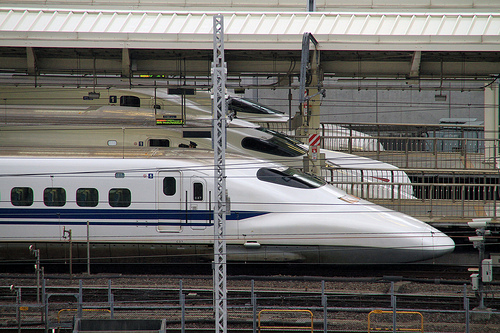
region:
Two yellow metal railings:
[254, 305, 426, 331]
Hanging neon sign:
[150, 82, 187, 129]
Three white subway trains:
[1, 77, 456, 271]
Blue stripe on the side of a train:
[1, 206, 268, 229]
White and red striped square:
[307, 130, 321, 147]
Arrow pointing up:
[107, 93, 118, 104]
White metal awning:
[1, 4, 498, 52]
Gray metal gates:
[250, 118, 498, 225]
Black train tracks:
[4, 280, 499, 315]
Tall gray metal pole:
[207, 14, 238, 331]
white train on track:
[1, 164, 478, 267]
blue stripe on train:
[12, 194, 239, 259]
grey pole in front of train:
[195, 63, 241, 323]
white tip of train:
[379, 193, 465, 255]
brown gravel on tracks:
[200, 273, 402, 305]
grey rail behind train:
[329, 154, 497, 236]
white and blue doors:
[151, 139, 186, 219]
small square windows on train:
[15, 181, 142, 206]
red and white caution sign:
[286, 131, 336, 168]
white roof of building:
[4, 6, 469, 62]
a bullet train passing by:
[1, 144, 462, 279]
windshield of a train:
[257, 159, 327, 194]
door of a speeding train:
[150, 166, 186, 236]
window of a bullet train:
[8, 182, 134, 210]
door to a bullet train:
[186, 175, 214, 231]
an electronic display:
[152, 114, 186, 130]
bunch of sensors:
[462, 211, 494, 320]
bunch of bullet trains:
[5, 79, 462, 267]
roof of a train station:
[7, 10, 484, 42]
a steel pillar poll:
[203, 9, 240, 331]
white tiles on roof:
[311, 7, 433, 49]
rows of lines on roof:
[54, 9, 131, 39]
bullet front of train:
[419, 222, 463, 254]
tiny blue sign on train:
[138, 170, 156, 182]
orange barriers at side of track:
[253, 297, 408, 331]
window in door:
[157, 172, 182, 202]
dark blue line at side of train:
[8, 207, 256, 228]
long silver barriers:
[329, 153, 481, 218]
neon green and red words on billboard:
[144, 116, 197, 128]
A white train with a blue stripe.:
[1, 153, 456, 267]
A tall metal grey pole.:
[212, 13, 229, 332]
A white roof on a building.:
[1, 2, 498, 53]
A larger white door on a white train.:
[155, 166, 184, 233]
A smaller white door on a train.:
[188, 175, 206, 229]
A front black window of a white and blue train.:
[253, 162, 325, 189]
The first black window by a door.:
[108, 187, 133, 207]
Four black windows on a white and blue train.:
[9, 186, 131, 209]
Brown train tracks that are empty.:
[3, 281, 498, 310]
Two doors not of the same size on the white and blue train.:
[155, 170, 208, 235]